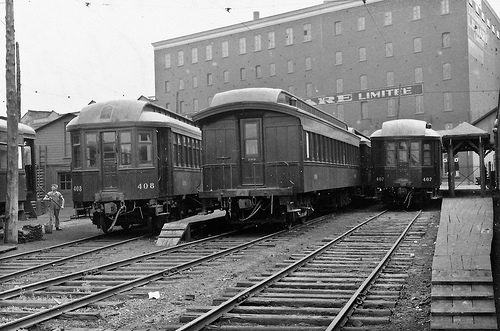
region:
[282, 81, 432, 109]
black and white sign on building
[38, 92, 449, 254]
three trains lined up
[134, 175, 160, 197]
White 408 on train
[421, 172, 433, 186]
white 407 on train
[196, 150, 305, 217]
area to stand on back of train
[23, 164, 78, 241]
a man washing the train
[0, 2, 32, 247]
a large wooden pole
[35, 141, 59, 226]
a ladder against the building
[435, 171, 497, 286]
a platform for passengers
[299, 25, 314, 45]
a missing window pane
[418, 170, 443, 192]
407 on the train car.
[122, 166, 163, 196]
408 on the train car.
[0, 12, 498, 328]
Taken in black and white.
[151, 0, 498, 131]
Building in the background.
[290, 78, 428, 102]
Sign on the building.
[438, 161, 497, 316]
Platform next to the train car.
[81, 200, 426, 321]
The train cars are on the tracks.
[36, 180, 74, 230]
There is one person in the shot.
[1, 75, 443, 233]
There are four train cars visible.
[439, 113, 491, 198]
Roof over part of the platform.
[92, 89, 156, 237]
passenger train car on wheels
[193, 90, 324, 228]
passenger train car on wheels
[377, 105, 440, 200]
passenger train car on wheels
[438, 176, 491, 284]
brick train station platform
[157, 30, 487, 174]
tall building in background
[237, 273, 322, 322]
wooden railroad ties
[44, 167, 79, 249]
man standing by train car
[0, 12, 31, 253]
tall palm tree on left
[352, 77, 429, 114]
English writing on building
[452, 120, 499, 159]
small roof on platform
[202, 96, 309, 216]
this is a container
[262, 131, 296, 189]
the container is black in color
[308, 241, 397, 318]
this is the railway line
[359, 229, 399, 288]
this is a metal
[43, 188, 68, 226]
this is a man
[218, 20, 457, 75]
this is a building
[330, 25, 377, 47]
this is the wall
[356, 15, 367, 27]
this is a window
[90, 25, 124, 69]
this is the sky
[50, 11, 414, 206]
the photo is in black and white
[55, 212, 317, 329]
train tracks are on the ground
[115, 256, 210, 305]
dirt is on the ground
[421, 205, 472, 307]
a staircase is next to the trains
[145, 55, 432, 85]
a building is behind the trains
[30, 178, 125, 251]
a man is holding a stick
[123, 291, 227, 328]
paper is on the ground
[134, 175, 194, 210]
numbers are on the train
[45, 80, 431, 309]
three trains are pictured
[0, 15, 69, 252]
a tree is next to the trains